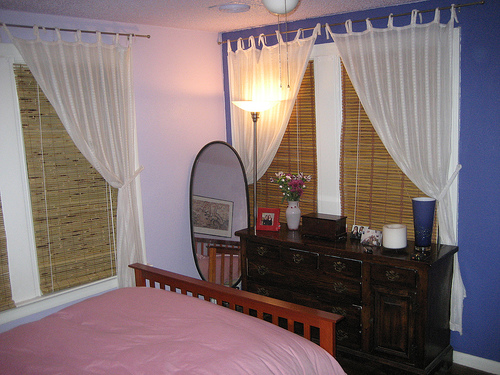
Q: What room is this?
A: A bedroom.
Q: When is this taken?
A: Night time.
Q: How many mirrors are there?
A: One.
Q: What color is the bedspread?
A: Pink.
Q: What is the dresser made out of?
A: Wood.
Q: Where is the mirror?
A: To the left of the dresser.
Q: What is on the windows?
A: Blinds.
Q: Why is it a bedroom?
A: It has a bed.